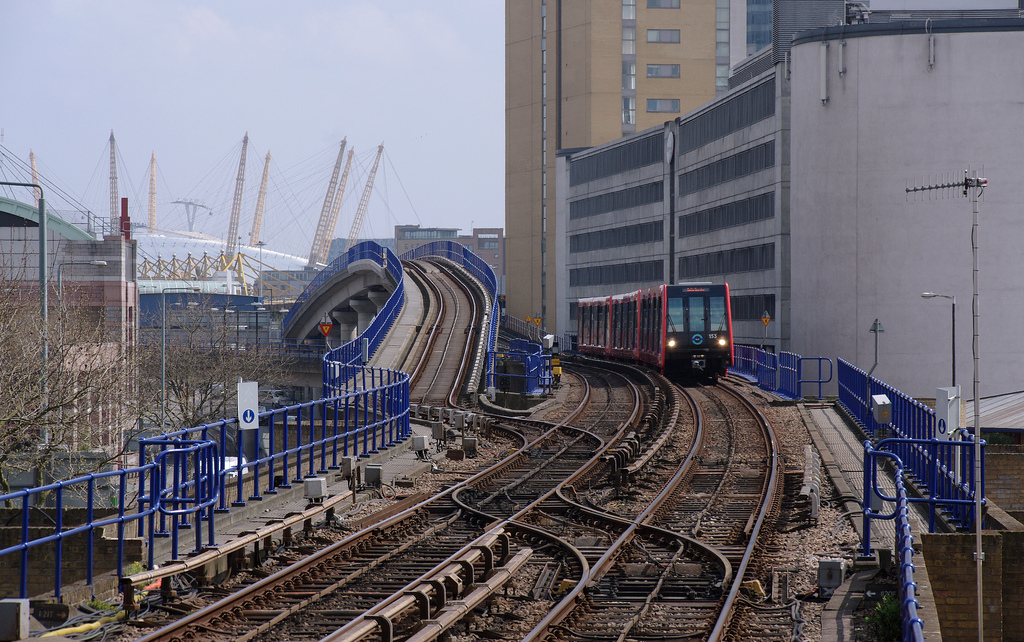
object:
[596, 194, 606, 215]
window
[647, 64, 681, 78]
window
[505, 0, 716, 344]
building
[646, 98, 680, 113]
window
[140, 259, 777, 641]
tracks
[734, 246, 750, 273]
window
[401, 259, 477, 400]
rail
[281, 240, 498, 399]
bridge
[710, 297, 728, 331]
window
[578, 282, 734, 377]
train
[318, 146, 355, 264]
crane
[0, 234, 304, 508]
leaves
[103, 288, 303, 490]
tree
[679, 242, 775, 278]
window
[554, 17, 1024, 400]
building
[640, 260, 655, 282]
window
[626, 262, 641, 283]
window